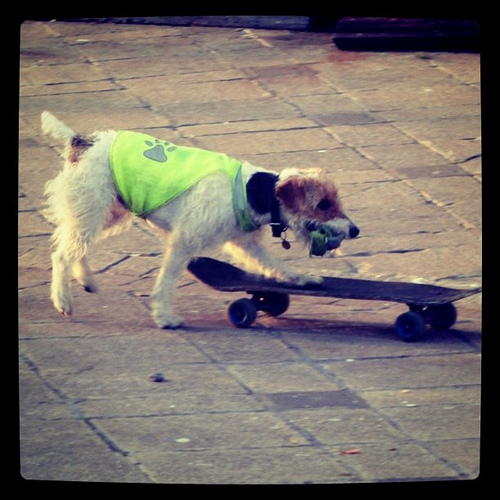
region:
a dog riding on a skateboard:
[37, 108, 482, 349]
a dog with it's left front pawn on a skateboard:
[28, 106, 482, 346]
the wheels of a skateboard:
[226, 295, 459, 343]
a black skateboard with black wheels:
[188, 254, 481, 349]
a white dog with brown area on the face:
[28, 109, 362, 335]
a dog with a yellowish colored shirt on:
[34, 105, 360, 342]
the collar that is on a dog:
[263, 170, 292, 252]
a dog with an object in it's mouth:
[38, 113, 362, 326]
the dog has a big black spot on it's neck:
[240, 163, 363, 260]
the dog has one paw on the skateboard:
[32, 83, 485, 355]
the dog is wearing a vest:
[20, 68, 367, 377]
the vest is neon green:
[35, 84, 349, 356]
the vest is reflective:
[46, 93, 354, 364]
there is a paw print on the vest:
[127, 124, 186, 174]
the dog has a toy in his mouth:
[271, 151, 372, 268]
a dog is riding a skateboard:
[23, 84, 498, 370]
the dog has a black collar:
[254, 176, 294, 254]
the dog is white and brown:
[27, 93, 402, 342]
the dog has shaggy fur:
[27, 100, 376, 367]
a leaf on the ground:
[337, 438, 365, 461]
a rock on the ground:
[151, 369, 173, 384]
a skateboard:
[172, 230, 471, 344]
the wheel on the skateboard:
[395, 309, 421, 341]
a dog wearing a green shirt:
[41, 110, 350, 342]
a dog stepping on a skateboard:
[36, 114, 462, 348]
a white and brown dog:
[35, 113, 365, 332]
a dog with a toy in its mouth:
[44, 113, 334, 330]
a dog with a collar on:
[242, 162, 359, 250]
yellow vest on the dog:
[108, 116, 253, 226]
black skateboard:
[189, 250, 479, 338]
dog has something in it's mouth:
[298, 218, 345, 260]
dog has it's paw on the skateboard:
[235, 243, 315, 300]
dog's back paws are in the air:
[33, 256, 112, 321]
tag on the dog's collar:
[278, 231, 293, 254]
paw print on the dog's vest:
[136, 131, 186, 168]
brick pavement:
[183, 51, 328, 137]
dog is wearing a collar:
[268, 173, 285, 251]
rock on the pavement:
[146, 364, 166, 389]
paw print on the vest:
[133, 133, 182, 165]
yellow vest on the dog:
[106, 131, 238, 197]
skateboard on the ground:
[190, 252, 499, 355]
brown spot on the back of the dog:
[70, 124, 100, 164]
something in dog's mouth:
[302, 229, 339, 252]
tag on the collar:
[274, 234, 291, 256]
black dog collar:
[264, 170, 285, 241]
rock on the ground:
[140, 353, 176, 410]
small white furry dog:
[38, 109, 359, 330]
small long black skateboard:
[184, 255, 481, 340]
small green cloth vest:
[111, 129, 241, 215]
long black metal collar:
[269, 171, 291, 246]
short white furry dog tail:
[41, 106, 75, 144]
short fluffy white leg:
[41, 151, 108, 312]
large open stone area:
[19, 14, 482, 482]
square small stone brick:
[89, 407, 313, 450]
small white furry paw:
[154, 303, 187, 330]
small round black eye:
[319, 194, 331, 209]